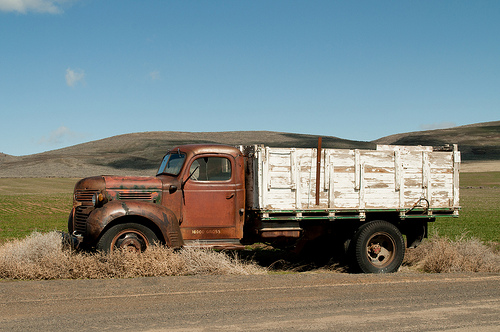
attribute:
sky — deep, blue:
[164, 35, 415, 105]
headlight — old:
[78, 191, 107, 206]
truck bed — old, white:
[241, 142, 461, 218]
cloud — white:
[58, 54, 89, 94]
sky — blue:
[1, 1, 496, 156]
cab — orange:
[73, 139, 248, 252]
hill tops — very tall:
[46, 73, 498, 176]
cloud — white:
[2, 0, 67, 18]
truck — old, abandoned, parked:
[71, 144, 460, 266]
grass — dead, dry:
[3, 233, 498, 274]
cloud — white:
[36, 121, 82, 151]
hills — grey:
[24, 115, 495, 175]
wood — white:
[300, 155, 414, 203]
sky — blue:
[210, 23, 401, 113]